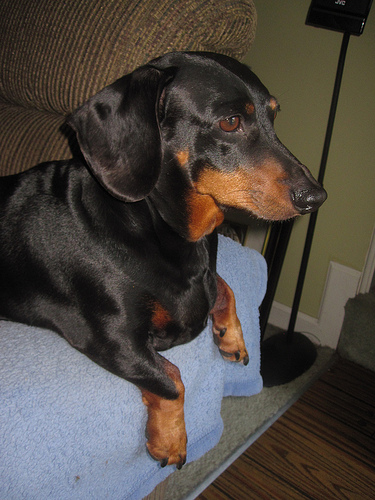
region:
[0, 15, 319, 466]
the dog is black in colour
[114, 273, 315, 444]
the paws are brown in colour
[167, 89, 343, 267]
the mouth is brown in colour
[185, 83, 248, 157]
the eyes are red in colour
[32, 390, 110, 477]
the sheet is white in colour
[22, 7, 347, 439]
the dog is on a sofa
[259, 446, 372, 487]
the floor is brown in colour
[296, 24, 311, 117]
the wall is green in colour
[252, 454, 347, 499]
the floor is wooden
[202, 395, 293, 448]
a carpet is on the floor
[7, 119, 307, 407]
A black and brown dog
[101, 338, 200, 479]
A black and brown dog's feet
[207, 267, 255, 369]
A black and brown dog's feet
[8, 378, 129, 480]
A blue dog's mat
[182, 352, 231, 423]
A blue dog's mat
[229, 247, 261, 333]
A blue dog's mat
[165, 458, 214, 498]
A grey floor mat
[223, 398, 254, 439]
A grey floor mat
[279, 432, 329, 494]
A wooden smooth brown floor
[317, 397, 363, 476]
A wooden smooth brown floor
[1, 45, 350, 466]
brown and black dog sitting on couch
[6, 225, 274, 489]
blue towel over couch for dog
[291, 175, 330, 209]
blue towel is nice and fluffy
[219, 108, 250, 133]
dog's eyes are amber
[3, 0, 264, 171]
couch is brown plaid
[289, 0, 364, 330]
vacuumer cleaner and they are black are great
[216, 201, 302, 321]
black bookshelve with no books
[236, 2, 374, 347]
green painted walls of living room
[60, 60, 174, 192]
large floppy ears of bugal type of dog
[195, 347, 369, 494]
wooden floor in kitchen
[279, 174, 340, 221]
nose of a dog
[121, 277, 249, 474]
paws of a dog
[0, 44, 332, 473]
dog laying on a bed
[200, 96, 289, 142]
eyes of a dog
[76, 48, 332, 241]
head of a dog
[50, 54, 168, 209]
ear of a dog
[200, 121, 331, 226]
the jaw of a dog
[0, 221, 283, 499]
a blue blanket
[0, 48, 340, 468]
dog is laying on a couch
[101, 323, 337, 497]
floor carpet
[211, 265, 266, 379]
brown paw of dog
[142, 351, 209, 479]
brown paw of dog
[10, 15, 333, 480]
black and brown dog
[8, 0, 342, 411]
dog sitting on chair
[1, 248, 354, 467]
dog sitting on arm chair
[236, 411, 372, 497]
wooden panels on floor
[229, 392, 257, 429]
white carpet on floor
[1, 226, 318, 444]
blue towel under dog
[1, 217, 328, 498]
blue tower on arm chair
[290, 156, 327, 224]
black nose of dog